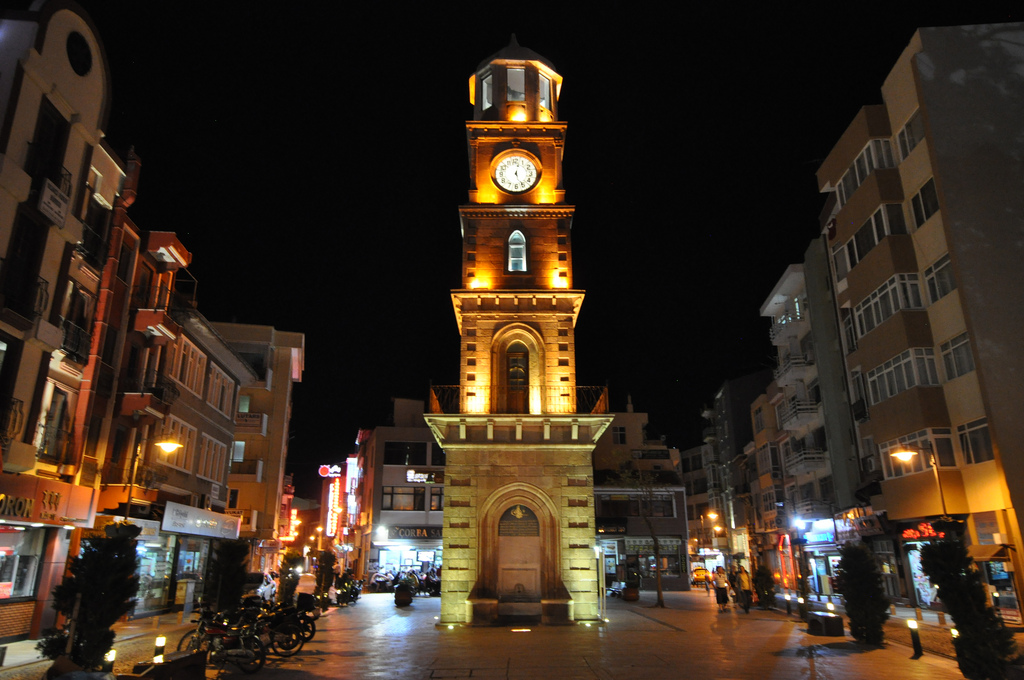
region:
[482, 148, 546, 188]
clock on top of the tower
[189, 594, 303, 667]
bike chained to the fence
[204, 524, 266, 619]
tree on the sidewalk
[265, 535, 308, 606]
tree on the sidewalk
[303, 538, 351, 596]
tree on the sidewalk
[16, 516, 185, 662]
tree on the sidewalk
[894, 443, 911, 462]
light on the pole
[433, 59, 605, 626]
Lights are on the tower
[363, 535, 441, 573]
Lights are blue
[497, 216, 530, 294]
The building has a window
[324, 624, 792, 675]
Sidewalk is wet with rain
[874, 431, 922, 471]
Light is yellow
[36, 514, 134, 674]
Tree is lime green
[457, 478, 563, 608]
The door on the tower has an arch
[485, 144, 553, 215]
The tower has a clock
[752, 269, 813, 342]
The building has a light on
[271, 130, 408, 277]
a view of dark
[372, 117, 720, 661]
a view of tower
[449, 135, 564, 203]
a clock in tower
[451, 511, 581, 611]
a view of door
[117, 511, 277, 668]
a view of door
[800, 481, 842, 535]
a view of lights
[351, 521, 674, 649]
light on the tower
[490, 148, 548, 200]
face of clock is white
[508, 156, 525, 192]
hands of clock are black in color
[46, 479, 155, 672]
tree on the sidewalk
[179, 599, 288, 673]
bikes locked up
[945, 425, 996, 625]
pole with light on top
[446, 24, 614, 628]
tower with clock on top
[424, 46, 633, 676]
Tower is lit up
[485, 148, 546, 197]
clock on building tower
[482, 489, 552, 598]
arched doorway on tower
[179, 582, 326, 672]
line of bicycles parked in front of store fronts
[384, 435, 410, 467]
A window on a building.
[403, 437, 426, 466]
A window on a building.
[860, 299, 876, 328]
A window on a building.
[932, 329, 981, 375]
A window on a building.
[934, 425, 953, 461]
A window on a building.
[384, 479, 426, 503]
A window on a building.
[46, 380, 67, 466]
A window on a building.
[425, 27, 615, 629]
A tall clock tower with arched door on the bottom.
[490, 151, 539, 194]
Round illuminated white and black clock.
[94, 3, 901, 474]
A dark black sky.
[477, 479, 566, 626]
Large arched doorway on the bottom of a tower.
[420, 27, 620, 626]
A clock tower with illuminated clock.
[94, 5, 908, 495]
A black sky above.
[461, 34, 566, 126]
Top of the clock tower with rectangle windows.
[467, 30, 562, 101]
Rounded roof with pointy top of a clock tower.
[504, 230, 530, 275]
Arched window under a clock.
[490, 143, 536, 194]
the clock face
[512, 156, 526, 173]
the minute hand of the clock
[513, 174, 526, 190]
the hour hand of the clock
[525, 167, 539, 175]
the 3 o'clock position of theclock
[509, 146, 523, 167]
the 12 o'clock position of theclock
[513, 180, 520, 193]
the 6 o'clock position of theclock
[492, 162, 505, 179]
the 9 o'clock position of theclock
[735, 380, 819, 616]
building on the side of the road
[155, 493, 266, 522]
the top of the sign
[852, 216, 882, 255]
A window on a building.